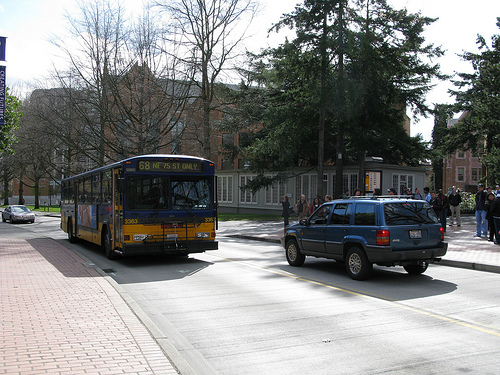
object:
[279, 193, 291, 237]
people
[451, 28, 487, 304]
side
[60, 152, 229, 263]
bus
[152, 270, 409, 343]
road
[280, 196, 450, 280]
car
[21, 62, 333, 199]
buildings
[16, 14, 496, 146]
background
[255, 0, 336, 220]
trees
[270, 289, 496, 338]
markings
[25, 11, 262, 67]
weather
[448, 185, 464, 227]
guy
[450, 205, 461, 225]
trousers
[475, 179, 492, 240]
guy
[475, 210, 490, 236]
jeans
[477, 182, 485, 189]
cap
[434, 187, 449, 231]
guy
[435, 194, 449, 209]
shirt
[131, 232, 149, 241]
headlights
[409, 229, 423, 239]
plates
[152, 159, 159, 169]
words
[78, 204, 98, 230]
sign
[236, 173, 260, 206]
windows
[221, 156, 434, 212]
building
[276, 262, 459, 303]
shadow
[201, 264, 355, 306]
ground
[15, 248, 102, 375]
sidewalk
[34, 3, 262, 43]
sunny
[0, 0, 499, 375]
picture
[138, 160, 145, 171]
number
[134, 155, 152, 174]
65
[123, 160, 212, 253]
front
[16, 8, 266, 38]
sky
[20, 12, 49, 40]
clouds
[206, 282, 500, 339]
street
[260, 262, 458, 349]
lanes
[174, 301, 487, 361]
surface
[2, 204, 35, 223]
car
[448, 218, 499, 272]
sidewalk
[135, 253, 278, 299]
asphalt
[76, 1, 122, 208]
tree